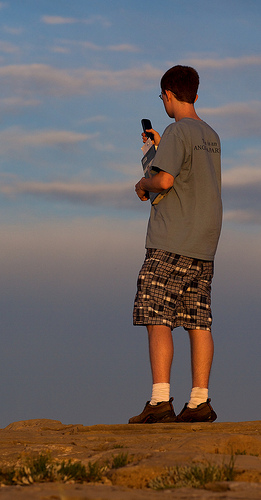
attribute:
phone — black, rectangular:
[141, 118, 154, 143]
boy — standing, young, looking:
[128, 64, 222, 424]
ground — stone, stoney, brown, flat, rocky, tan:
[1, 418, 260, 498]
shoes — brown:
[129, 397, 217, 423]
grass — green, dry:
[1, 453, 248, 484]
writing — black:
[192, 138, 218, 154]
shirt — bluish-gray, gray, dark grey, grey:
[145, 119, 223, 260]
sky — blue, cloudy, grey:
[1, 1, 260, 423]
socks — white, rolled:
[148, 383, 208, 408]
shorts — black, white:
[131, 248, 214, 331]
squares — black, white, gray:
[131, 250, 213, 330]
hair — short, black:
[160, 64, 200, 103]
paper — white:
[140, 137, 153, 155]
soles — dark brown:
[129, 408, 217, 422]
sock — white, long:
[149, 383, 171, 406]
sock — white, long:
[188, 386, 208, 411]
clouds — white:
[3, 15, 259, 214]